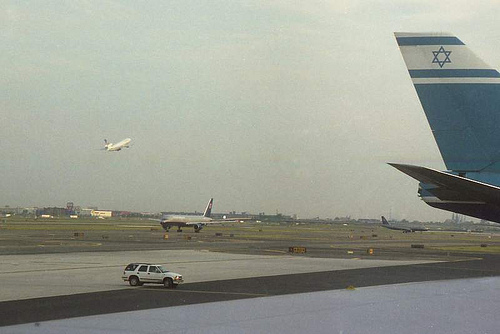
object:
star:
[431, 46, 452, 68]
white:
[393, 31, 500, 84]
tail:
[203, 198, 213, 217]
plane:
[149, 197, 252, 232]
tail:
[104, 139, 113, 149]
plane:
[104, 138, 132, 152]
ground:
[0, 216, 497, 334]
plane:
[380, 216, 430, 234]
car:
[122, 263, 185, 289]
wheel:
[129, 276, 139, 286]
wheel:
[164, 278, 173, 288]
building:
[81, 209, 113, 220]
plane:
[383, 32, 500, 224]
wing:
[186, 221, 237, 225]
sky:
[0, 1, 215, 92]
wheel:
[177, 229, 183, 232]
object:
[347, 251, 354, 255]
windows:
[125, 263, 139, 271]